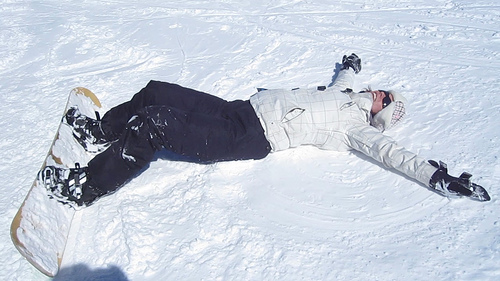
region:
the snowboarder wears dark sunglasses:
[381, 85, 392, 112]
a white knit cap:
[371, 84, 411, 134]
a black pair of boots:
[38, 105, 115, 217]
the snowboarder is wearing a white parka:
[247, 64, 444, 192]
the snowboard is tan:
[8, 80, 105, 279]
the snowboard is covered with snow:
[8, 82, 107, 279]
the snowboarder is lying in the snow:
[32, 44, 494, 209]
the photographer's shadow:
[45, 259, 132, 279]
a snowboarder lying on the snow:
[11, 13, 491, 270]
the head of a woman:
[357, 80, 412, 130]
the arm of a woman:
[361, 127, 491, 228]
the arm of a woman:
[306, 38, 369, 94]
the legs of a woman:
[41, 81, 257, 203]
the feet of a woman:
[30, 103, 94, 213]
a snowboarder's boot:
[38, 161, 104, 216]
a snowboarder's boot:
[56, 105, 103, 153]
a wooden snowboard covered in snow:
[8, 87, 108, 278]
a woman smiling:
[363, 80, 407, 120]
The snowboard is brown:
[21, 74, 96, 276]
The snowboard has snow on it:
[1, 55, 123, 279]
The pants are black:
[67, 68, 269, 213]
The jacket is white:
[249, 48, 459, 218]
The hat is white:
[366, 76, 411, 132]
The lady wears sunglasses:
[369, 81, 403, 127]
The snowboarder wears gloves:
[328, 44, 368, 80]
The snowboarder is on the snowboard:
[20, 41, 492, 278]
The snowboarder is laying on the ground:
[16, 34, 498, 274]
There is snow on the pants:
[95, 94, 210, 181]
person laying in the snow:
[0, 36, 470, 279]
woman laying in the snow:
[3, 30, 492, 280]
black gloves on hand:
[338, 45, 365, 69]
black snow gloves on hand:
[426, 165, 498, 207]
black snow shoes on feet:
[43, 112, 110, 195]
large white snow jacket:
[278, 67, 358, 152]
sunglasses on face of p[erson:
[380, 85, 395, 109]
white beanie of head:
[382, 88, 407, 122]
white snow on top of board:
[0, 180, 82, 262]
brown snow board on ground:
[6, 73, 106, 277]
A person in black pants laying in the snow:
[0, 45, 495, 275]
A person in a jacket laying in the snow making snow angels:
[0, 45, 495, 270]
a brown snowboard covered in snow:
[0, 80, 106, 276]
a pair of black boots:
[35, 100, 100, 220]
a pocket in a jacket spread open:
[276, 101, 306, 126]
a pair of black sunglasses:
[380, 85, 392, 110]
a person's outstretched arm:
[355, 128, 489, 203]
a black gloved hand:
[330, 43, 365, 73]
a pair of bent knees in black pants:
[122, 76, 182, 161]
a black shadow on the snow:
[45, 260, 130, 280]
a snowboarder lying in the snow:
[39, 52, 491, 209]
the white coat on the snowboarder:
[248, 66, 437, 188]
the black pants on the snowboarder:
[86, 78, 271, 205]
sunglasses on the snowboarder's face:
[380, 88, 392, 108]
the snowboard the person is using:
[10, 84, 102, 279]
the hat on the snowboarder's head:
[372, 88, 405, 131]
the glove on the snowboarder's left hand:
[429, 166, 491, 200]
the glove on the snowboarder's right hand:
[339, 53, 361, 73]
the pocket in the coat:
[280, 106, 305, 124]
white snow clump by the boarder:
[403, 78, 410, 88]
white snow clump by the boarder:
[172, 180, 186, 196]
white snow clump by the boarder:
[156, 211, 172, 228]